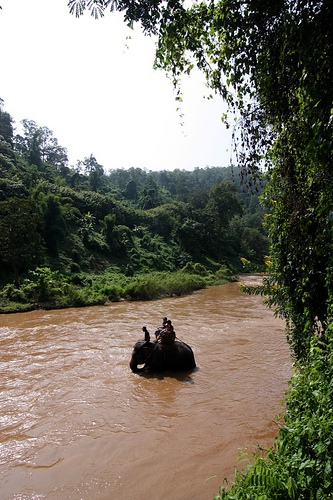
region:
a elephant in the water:
[99, 319, 204, 399]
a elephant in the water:
[97, 286, 234, 390]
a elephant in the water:
[115, 309, 213, 369]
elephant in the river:
[104, 289, 242, 395]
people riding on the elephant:
[118, 310, 238, 403]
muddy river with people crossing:
[52, 247, 251, 413]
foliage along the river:
[247, 395, 322, 484]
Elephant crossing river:
[119, 304, 211, 405]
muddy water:
[43, 422, 132, 490]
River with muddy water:
[70, 264, 219, 419]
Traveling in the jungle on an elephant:
[91, 304, 220, 396]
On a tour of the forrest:
[82, 285, 287, 434]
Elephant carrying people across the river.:
[117, 307, 226, 416]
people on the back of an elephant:
[122, 312, 203, 384]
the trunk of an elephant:
[126, 359, 140, 372]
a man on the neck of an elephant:
[125, 325, 151, 374]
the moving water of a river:
[6, 318, 82, 402]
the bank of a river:
[0, 286, 152, 312]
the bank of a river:
[137, 277, 207, 305]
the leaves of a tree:
[276, 146, 312, 247]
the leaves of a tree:
[25, 123, 45, 162]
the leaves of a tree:
[212, 192, 228, 226]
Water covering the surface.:
[0, 269, 297, 499]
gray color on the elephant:
[128, 337, 198, 381]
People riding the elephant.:
[151, 314, 178, 349]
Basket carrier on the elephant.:
[153, 325, 177, 344]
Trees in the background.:
[3, 99, 264, 312]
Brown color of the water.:
[0, 264, 290, 497]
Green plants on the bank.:
[213, 336, 331, 499]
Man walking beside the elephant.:
[138, 320, 150, 343]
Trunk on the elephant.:
[127, 346, 143, 374]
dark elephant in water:
[120, 316, 195, 385]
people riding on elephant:
[143, 300, 188, 350]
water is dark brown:
[12, 391, 120, 477]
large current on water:
[6, 329, 106, 467]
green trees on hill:
[3, 210, 191, 290]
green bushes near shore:
[46, 269, 211, 309]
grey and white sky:
[44, 53, 213, 160]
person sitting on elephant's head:
[124, 318, 152, 357]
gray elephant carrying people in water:
[124, 312, 197, 383]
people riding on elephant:
[128, 310, 183, 347]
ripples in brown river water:
[148, 435, 183, 452]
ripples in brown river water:
[114, 442, 148, 469]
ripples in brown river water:
[221, 358, 243, 388]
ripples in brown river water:
[63, 442, 98, 472]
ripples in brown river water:
[53, 354, 83, 378]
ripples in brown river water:
[58, 434, 91, 461]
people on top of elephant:
[131, 312, 179, 346]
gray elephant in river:
[127, 339, 201, 380]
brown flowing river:
[5, 288, 291, 481]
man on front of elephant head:
[137, 321, 153, 351]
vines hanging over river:
[69, 3, 328, 216]